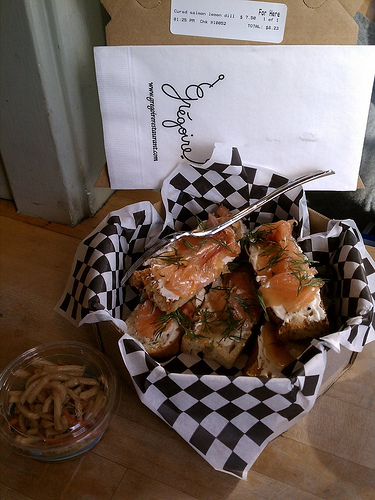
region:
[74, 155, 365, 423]
Sandwiches on a basket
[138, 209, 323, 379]
Sandwiches has white cream cheese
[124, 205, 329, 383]
Sandwiches have slices of meat on top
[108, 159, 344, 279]
Spoon on the basket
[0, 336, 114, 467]
Cup of salad next to basket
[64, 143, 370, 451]
Food is over checkered Napkin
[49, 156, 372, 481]
Checkered Napkin is white and black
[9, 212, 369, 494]
Basket is on the floor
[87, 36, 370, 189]
White printed paper behind basket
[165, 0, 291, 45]
White label with black lettes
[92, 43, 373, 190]
White envelope with black type on it.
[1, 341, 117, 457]
Plastic container with food inside.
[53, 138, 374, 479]
Black and white checked paper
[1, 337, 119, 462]
Plastic container with lid on it.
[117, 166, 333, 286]
Silver fork.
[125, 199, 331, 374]
Slices of food.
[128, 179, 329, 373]
Food with salmon, cream cheese and rosemary on it.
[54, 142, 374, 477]
Food in a paper lined container.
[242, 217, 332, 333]
Slice of food sprinkled with rosemary.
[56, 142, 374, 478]
Container of food with a fork in it.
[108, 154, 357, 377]
a basket of food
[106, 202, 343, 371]
salmon on toast with cream cheese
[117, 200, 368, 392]
salmon with herbs on top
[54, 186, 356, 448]
a basket with a checkered liner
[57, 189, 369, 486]
a white and black checkered liner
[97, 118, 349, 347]
a silver fork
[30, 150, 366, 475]
food sitting on a wooden table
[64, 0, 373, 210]
to go boxes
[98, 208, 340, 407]
bread with lox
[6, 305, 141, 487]
an appetizer on a wooden table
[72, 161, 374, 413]
The box is lined with paper.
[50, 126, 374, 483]
Paper has black checks.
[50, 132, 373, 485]
Paper has white checks.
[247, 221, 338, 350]
Bagel bite with cream cheese and lox.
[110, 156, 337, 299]
Spoon sticking out of box.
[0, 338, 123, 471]
Noodles in a container.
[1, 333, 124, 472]
Container is clear plastic.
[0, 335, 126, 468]
Lid is on container.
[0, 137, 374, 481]
Food on floor in front of door.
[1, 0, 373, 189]
Cardboard box beside bagel bites.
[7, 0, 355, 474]
a meal sitting on a table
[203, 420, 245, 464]
a black and white checkered paper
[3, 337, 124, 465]
a plastic container of noodles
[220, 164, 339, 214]
a silver fork handle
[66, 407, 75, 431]
a slice of carrot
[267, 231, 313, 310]
salmon sushi on bread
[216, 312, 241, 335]
herbs sprinkled on sushi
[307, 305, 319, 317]
cream cheese on bread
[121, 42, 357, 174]
a white napkin leaning on cardboard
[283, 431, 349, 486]
wooden table holding a dish